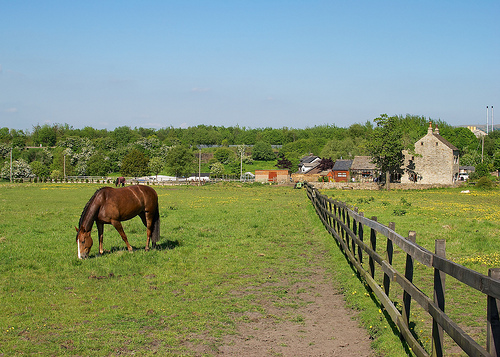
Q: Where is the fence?
A: To the right.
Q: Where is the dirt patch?
A: In the pasture.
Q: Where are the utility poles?
A: By the trees and buildings.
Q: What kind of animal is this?
A: Horse.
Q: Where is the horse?
A: Green field.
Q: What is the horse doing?
A: Grazing.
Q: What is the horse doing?
A: Eating grass.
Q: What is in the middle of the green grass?
A: Wooden fence.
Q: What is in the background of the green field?
A: Houses.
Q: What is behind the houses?
A: Tall green trees.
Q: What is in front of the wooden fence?
A: Dirt patch.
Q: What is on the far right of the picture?
A: Street lamp.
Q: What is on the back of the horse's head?
A: Horse mane.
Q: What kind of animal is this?
A: Horse.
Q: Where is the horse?
A: Green field.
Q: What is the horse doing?
A: Grazing.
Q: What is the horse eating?
A: Grass.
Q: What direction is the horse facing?
A: Left.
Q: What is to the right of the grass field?
A: Wooden fence.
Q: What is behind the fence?
A: Row of houses.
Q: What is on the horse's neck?
A: Mane.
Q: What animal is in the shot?
A: Horse.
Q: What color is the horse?
A: Brown.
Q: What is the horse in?
A: Pasture.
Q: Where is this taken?
A: Pasture.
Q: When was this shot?
A: Daytime.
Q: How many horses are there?
A: 2.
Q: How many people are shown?
A: 0.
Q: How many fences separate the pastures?
A: 1.